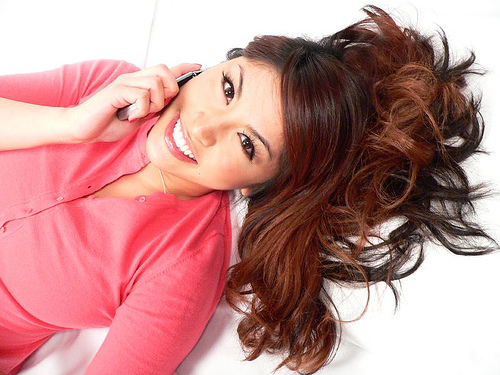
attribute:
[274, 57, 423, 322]
hair — long, auburn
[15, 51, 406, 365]
woman — smiling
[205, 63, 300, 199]
eyes — brown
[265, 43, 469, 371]
hair — spread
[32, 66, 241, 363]
shirt — salmon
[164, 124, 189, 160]
teeth — white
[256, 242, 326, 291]
hair — brown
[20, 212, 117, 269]
shirt — pink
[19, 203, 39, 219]
button — small, shiny pink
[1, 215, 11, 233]
button — shiny pink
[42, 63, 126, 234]
shirt — salmon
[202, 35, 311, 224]
eyebrows — thin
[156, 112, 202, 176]
gloss — pink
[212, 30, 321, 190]
lashes — full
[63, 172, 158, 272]
shirt — pink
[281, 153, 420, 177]
hair — brown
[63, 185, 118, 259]
shirt — pink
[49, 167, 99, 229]
shirt — pink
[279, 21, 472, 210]
hair — woman's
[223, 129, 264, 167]
eye — dark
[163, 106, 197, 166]
lips — red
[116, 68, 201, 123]
phone — silver and black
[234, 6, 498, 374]
hair — brown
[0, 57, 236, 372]
shirt — pink 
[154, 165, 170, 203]
necklace — white 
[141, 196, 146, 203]
button — pink , small 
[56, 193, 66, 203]
button — pink , small 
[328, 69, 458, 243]
hair — brown